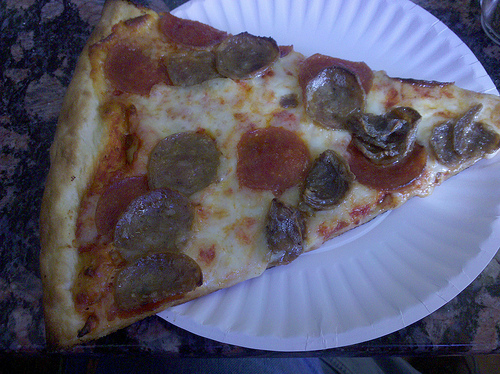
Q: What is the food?
A: Pizza.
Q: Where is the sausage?
A: On the pizza.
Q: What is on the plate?
A: Pizza.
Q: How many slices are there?
A: One.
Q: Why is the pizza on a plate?
A: So someone can eat it.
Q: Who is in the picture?
A: No one.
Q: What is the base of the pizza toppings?
A: Cheese.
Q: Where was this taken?
A: Inside on a table.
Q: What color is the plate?
A: White.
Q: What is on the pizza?
A: Pepperoni and sausage.